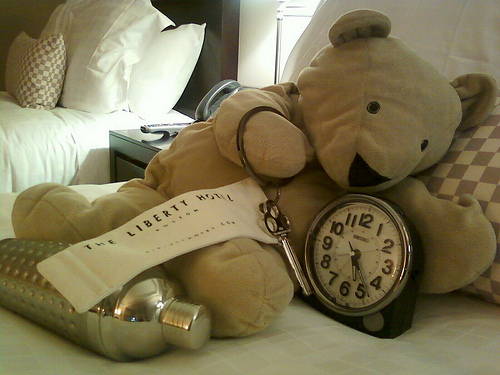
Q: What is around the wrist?
A: Key.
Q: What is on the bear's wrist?
A: A key on a ring.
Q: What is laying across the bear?
A: A napkin.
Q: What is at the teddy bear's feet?
A: A cocktail shaker.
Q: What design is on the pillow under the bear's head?
A: Checkered.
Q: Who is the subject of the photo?
A: The beige stuffed bear.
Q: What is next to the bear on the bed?
A: An old clock.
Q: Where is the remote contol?
A: On the nightstand.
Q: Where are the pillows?
A: On the bed.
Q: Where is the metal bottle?
A: On the bed.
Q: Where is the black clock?
A: On the bed.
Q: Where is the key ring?
A: On the teddy bear's arm.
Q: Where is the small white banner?
A: On the teddy bear.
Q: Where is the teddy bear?
A: On the bed.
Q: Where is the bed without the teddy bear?
A: Next to the nightstand.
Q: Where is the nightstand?
A: Next to the beds.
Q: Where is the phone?
A: On the nightstand.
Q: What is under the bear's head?
A: A checkered pillow.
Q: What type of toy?
A: Bear.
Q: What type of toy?
A: Bear.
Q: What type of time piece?
A: Clock.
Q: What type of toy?
A: Bear.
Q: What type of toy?
A: Bear.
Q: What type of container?
A: Flask.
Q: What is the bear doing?
A: Laying down.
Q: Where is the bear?
A: The bed.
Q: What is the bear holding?
A: A clock.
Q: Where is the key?
A: Bears wrist.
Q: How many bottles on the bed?
A: One.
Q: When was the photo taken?
A: Day time.